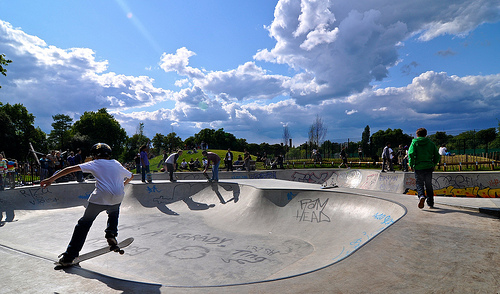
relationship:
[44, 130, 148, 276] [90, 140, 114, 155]
person wearing helmet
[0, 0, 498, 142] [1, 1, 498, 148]
clouds in sky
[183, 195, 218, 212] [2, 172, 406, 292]
shadow on ramp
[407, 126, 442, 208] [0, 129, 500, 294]
person at skate park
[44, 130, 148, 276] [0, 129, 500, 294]
person at skate park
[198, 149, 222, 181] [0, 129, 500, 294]
person at skate park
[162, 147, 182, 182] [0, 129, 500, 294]
person at skate park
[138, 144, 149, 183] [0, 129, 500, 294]
person at skate park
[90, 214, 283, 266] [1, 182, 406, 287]
graffiti inside rink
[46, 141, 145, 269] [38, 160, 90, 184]
boy holding out arm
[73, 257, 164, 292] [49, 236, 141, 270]
shadow of skate board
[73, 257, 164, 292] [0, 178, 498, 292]
shadow on ground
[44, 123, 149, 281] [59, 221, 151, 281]
person on skate board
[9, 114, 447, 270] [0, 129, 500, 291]
people at skate park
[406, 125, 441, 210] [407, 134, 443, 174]
boy wearing sweater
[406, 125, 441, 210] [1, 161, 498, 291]
boy skateboarding at park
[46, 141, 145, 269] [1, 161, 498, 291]
boy skateboarding at park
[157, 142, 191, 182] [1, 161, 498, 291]
boy skateboarding at park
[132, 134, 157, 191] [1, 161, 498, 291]
boy skateboarding at park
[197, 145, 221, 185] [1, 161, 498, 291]
boy skateboarding at park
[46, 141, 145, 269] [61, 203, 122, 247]
boy wearing jeans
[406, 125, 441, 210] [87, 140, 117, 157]
boy wearing helmet